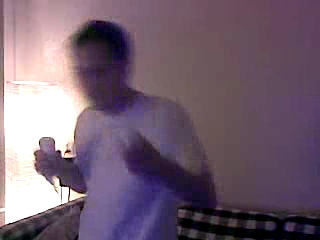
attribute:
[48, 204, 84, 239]
cat — gray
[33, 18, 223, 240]
man — blurry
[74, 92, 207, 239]
shirt — blurry, white, here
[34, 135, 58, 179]
remote — controller, blurry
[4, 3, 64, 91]
window — bright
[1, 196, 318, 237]
sofa — black, white, here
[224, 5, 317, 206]
wall — white